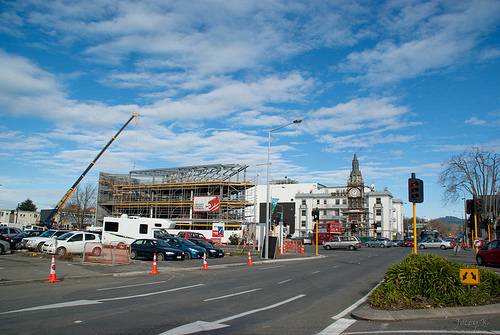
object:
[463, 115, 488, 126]
cloud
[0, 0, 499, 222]
sky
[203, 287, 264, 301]
line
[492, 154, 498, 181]
limb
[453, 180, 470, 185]
limb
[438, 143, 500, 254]
tree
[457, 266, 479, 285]
sign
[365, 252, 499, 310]
bushes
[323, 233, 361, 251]
car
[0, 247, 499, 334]
ground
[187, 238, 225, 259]
car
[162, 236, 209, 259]
car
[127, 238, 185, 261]
car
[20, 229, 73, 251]
car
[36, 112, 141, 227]
crane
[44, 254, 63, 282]
cone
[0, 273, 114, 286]
curb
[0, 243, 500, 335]
street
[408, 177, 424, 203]
sign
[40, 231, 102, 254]
car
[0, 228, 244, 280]
parking lot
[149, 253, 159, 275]
cone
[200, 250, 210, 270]
cone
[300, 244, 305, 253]
cone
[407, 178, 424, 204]
traffic light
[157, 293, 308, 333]
arrow